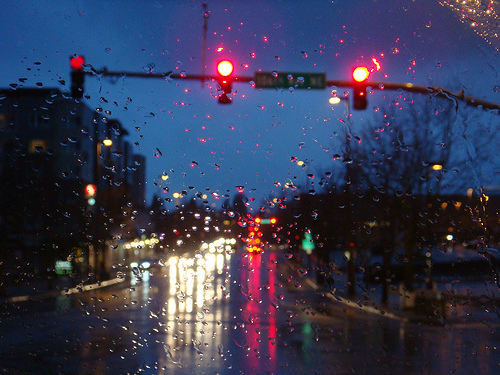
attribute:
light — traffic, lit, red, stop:
[214, 58, 235, 93]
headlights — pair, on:
[126, 259, 153, 270]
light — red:
[212, 60, 233, 106]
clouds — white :
[219, 120, 256, 155]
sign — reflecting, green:
[301, 232, 316, 254]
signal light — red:
[201, 38, 262, 124]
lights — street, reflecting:
[163, 244, 280, 330]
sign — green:
[254, 70, 329, 90]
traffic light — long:
[63, 47, 380, 124]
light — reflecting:
[114, 218, 245, 373]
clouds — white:
[86, 23, 148, 59]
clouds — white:
[147, 24, 237, 66]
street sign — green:
[251, 67, 331, 96]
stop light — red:
[252, 214, 262, 238]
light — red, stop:
[206, 41, 373, 103]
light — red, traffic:
[343, 53, 398, 151]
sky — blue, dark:
[0, 2, 498, 214]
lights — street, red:
[253, 212, 277, 227]